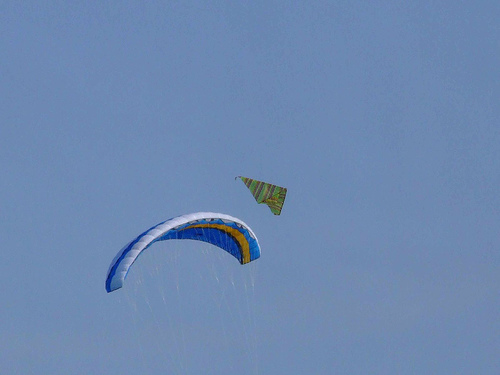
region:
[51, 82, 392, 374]
a parachute and kite in air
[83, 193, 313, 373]
many strings attached to parachute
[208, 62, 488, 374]
kite flying high in the sky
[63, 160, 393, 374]
a blue, white, and yellow parachute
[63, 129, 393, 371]
kite flying higher than a parachute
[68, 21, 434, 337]
clear dull blue sky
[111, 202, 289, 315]
white rim of parachute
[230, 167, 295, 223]
a thin corner on a kite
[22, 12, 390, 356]
a sky with no coulds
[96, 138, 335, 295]
Two kites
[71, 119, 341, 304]
The kites are in the air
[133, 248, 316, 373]
The kites are connected to string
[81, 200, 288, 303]
This kite is shaped like a semi-circle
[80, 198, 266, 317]
This kite is blue, yellow, and white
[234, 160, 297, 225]
This kite is green and red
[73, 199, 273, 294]
This kite is to the left of the smaller kite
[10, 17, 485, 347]
There are no clouds in the sky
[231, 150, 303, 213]
This kite is flown higher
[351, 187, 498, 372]
A light blue sky cover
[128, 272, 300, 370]
A light blue sky cover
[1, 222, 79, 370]
A light blue sky cover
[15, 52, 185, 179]
A light blue sky cover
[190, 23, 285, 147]
A light blue sky cover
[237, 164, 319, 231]
A kite up the sky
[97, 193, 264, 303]
A kite up the sky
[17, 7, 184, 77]
A kite up the sky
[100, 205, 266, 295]
wind sail in the sky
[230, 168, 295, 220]
kite in the sky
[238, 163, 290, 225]
colorful striped kite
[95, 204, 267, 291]
a parasail in the sky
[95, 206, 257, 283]
blue, yellow, black and white parasail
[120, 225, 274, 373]
strings that attach to the parasail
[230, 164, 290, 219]
a kite flying in the sky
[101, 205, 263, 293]
arched shape windsail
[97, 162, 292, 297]
two different flying objects in the sky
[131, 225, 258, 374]
the strings to the sail are visible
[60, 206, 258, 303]
kite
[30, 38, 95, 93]
white clouds in blue sky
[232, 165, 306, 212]
flag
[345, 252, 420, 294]
white clouds in blue sky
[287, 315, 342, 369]
white clouds in blue sky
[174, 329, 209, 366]
white clouds in blue sky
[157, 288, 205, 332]
white clouds in blue sky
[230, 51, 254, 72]
white clouds in blue sky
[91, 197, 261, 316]
blue open arc parachute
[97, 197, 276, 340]
open blue arc parachute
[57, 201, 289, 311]
blue parachute with white tie lines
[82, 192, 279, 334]
open parachute sailing through sky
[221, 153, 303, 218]
green kite by parachute